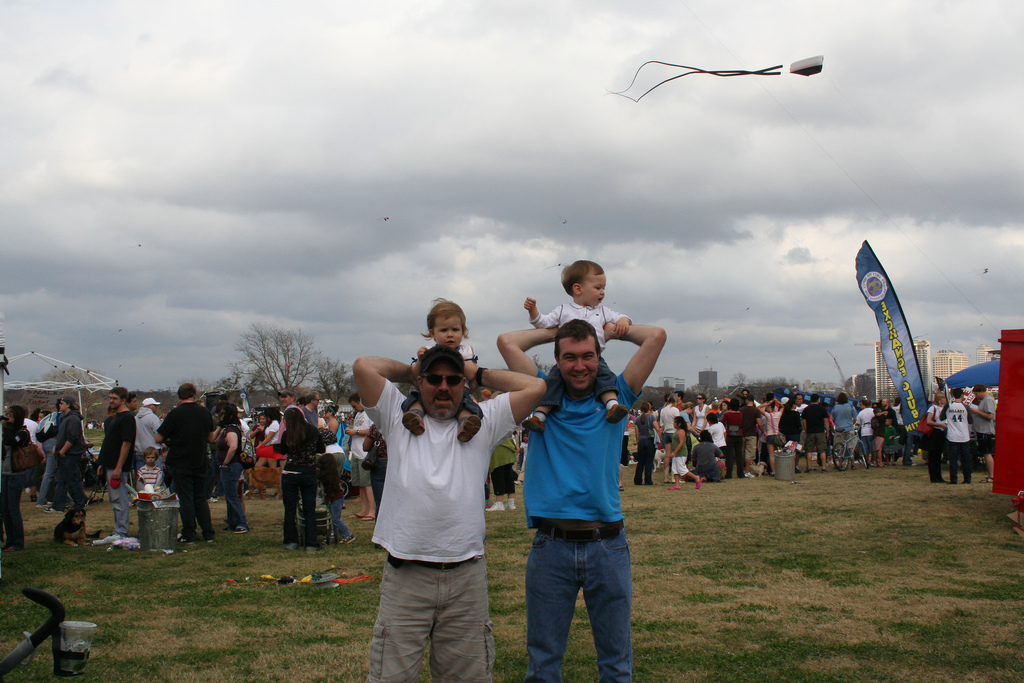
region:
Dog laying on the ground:
[46, 487, 101, 554]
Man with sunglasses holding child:
[354, 293, 551, 676]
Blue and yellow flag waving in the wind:
[833, 233, 947, 430]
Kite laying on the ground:
[220, 549, 382, 620]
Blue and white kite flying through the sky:
[588, 45, 844, 115]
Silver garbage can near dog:
[124, 490, 191, 554]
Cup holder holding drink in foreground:
[51, 612, 102, 676]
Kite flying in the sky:
[602, 50, 830, 105]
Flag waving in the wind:
[838, 234, 940, 434]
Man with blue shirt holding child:
[494, 256, 654, 672]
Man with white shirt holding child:
[345, 288, 543, 671]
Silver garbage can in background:
[122, 485, 186, 555]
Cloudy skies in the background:
[11, 0, 1017, 308]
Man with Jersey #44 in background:
[933, 378, 976, 478]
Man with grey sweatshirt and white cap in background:
[130, 391, 160, 449]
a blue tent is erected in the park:
[939, 350, 1003, 496]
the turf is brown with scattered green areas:
[16, 470, 1020, 676]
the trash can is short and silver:
[135, 490, 184, 560]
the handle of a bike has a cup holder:
[0, 579, 103, 679]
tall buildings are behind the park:
[778, 334, 1007, 490]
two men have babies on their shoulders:
[344, 253, 671, 674]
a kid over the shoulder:
[336, 275, 546, 674]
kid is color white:
[512, 238, 633, 428]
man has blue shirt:
[495, 298, 680, 678]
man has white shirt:
[340, 344, 550, 673]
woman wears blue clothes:
[261, 394, 328, 562]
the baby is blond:
[398, 279, 484, 359]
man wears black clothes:
[161, 372, 222, 550]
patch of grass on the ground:
[672, 488, 949, 660]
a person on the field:
[494, 291, 698, 557]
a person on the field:
[348, 323, 450, 539]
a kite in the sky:
[590, 39, 825, 106]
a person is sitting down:
[401, 283, 487, 442]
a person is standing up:
[345, 333, 524, 676]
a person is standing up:
[484, 289, 682, 679]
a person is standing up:
[146, 380, 224, 535]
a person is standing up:
[272, 403, 323, 534]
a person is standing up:
[23, 390, 100, 533]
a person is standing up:
[938, 377, 974, 476]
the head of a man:
[400, 326, 473, 422]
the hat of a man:
[421, 341, 467, 376]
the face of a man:
[387, 355, 467, 412]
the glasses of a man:
[424, 353, 476, 399]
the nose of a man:
[427, 376, 453, 396]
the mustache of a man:
[424, 379, 456, 402]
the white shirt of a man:
[356, 397, 508, 560]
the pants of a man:
[371, 552, 496, 680]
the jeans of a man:
[538, 502, 655, 677]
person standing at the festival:
[348, 338, 511, 675]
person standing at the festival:
[491, 314, 662, 669]